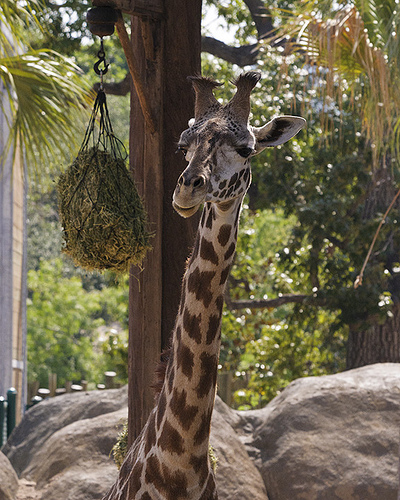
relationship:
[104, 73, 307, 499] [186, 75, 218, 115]
giraffe has horn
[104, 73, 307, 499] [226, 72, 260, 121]
giraffe has horn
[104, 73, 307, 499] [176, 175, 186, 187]
giraffe has nostril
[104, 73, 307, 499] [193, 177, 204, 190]
giraffe has nostril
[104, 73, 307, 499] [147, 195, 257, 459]
giraffe has neck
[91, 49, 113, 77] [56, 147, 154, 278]
hook holding hay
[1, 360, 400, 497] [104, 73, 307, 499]
rocks behind giraffe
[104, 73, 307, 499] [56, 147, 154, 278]
giraffe looking at hay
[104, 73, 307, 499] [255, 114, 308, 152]
giraffe has ear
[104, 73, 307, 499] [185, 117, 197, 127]
giraffe has ear